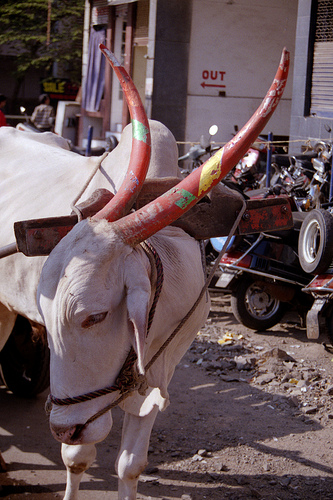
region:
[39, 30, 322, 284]
the goats horns are long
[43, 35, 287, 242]
the horns are painted red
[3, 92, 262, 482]
the goat is white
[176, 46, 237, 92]
the word out is written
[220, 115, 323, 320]
a pile of junk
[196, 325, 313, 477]
garbage on the street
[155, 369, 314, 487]
shadow of the cart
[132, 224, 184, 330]
a rope around the goats neck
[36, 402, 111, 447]
the nose is pink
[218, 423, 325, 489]
the sun is on the floor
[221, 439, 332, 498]
ground covered in rocks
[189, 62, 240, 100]
red writing on side of wall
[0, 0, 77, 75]
large tree with green leaves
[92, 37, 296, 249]
red horns on animal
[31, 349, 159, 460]
brown rope harness on animal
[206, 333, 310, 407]
trash laying on ground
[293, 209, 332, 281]
tire with white rim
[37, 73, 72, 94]
store sign with yellow writing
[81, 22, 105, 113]
purple curtain in window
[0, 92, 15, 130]
person in red shirt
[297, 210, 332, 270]
a used tire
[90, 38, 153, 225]
a painted horn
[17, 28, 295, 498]
A goat with painted horns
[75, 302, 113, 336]
the eye of a goat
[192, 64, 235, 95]
red sign reading "out"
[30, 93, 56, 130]
man in brown shirt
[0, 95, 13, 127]
a man in a red shirt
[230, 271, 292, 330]
rear tire of a motorcycle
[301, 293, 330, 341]
a mudflap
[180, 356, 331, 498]
rocks and dirt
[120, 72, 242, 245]
RED DECORATED HORNS ON EXOTIC ANIMAL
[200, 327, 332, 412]
LITTERED DIRT IN RURAL AREA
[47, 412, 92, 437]
PINK NOSE OF EXOTIC ANIMAL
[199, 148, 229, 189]
YELLOW PAINT ON RED HORN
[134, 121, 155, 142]
GREEN PAINT ON RED HORN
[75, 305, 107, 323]
SLANTED ALIENLIKE EYE ON ANIMAL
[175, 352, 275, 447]
SHAWDOW CAST BY CART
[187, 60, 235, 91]
OUT TO THE LEFT RED SIGN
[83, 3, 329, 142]
WHITE BUILDING IN BACKGROUND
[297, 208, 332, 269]
BLACK RUBBER TIRE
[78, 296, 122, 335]
large eye of a cow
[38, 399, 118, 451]
nose of a white cow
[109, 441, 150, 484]
a knee of a cow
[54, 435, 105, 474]
knee on a cow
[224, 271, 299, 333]
tire with metal rim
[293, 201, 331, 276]
tire with metal rim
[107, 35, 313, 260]
cow horn painted red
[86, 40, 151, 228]
cow horn painted red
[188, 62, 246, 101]
red letters on a white wall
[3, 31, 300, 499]
white cow with painted horns